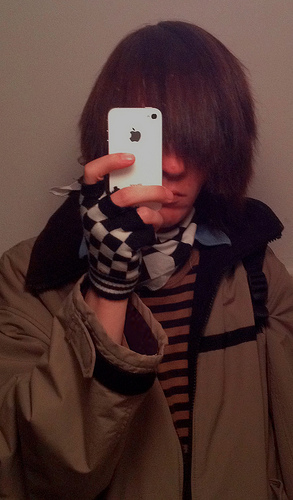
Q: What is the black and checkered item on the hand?
A: A glove.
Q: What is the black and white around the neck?
A: A scarf.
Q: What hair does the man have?
A: Brown.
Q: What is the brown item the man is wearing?
A: A jacket.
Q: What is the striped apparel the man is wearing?
A: A shirt.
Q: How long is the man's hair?
A: Shoulder length.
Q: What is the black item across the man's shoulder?
A: A strap.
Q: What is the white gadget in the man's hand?
A: An iphone.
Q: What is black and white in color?
A: The fingerless gloves.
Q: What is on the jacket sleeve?
A: The velcro.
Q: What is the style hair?
A: The mop top.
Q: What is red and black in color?
A: The striped shirt.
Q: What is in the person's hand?
A: The iPhone.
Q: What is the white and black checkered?
A: The fingerless gloves.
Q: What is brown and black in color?
A: The jacket.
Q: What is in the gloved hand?
A: The white iPhone.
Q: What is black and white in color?
A: The checkerboard glove.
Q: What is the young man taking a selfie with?
A: The smartphone.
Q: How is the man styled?
A: Young man with long hair covering his face.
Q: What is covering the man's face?
A: Long hair covering boys face.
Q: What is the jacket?
A: Beige colored jacket with black trim.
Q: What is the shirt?
A: Beige and black horizontal striped shirt.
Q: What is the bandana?
A: Black and white bandanna around neck.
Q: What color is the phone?
A: White.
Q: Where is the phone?
A: In the boy's hand.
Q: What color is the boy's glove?
A: Black and white.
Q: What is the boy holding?
A: The phone.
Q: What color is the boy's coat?
A: Tan and black.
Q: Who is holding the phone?
A: The boy.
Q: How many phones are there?
A: One.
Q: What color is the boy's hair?
A: Brown.